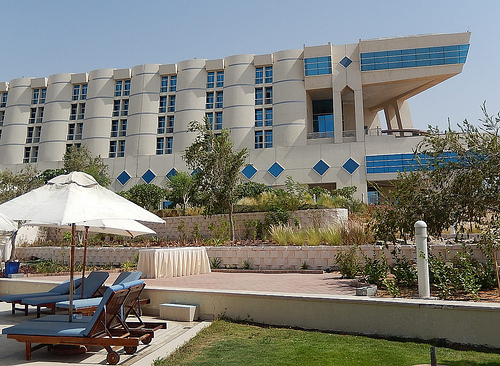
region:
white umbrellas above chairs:
[22, 177, 148, 239]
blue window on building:
[306, 52, 336, 81]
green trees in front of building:
[403, 165, 490, 217]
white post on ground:
[406, 216, 431, 303]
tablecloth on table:
[130, 239, 225, 284]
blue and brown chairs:
[2, 282, 169, 352]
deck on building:
[305, 130, 336, 149]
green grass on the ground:
[218, 320, 310, 355]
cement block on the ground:
[352, 283, 383, 305]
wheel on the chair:
[91, 350, 135, 364]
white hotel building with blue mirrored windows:
[0, 28, 497, 213]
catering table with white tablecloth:
[133, 245, 212, 277]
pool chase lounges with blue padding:
[1, 268, 166, 363]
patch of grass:
[148, 315, 498, 365]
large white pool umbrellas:
[2, 170, 167, 342]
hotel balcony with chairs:
[364, 73, 461, 135]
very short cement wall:
[0, 276, 498, 347]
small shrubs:
[333, 243, 497, 298]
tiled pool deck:
[0, 294, 200, 364]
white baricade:
[412, 218, 432, 298]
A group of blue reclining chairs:
[2, 261, 168, 361]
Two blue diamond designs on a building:
[309, 151, 363, 179]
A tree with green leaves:
[176, 118, 268, 244]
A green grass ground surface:
[216, 323, 309, 365]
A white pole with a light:
[402, 216, 435, 301]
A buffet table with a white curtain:
[135, 243, 217, 280]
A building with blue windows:
[5, 28, 497, 210]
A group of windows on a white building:
[21, 56, 299, 103]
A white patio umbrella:
[0, 147, 171, 227]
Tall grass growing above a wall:
[266, 217, 352, 266]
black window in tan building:
[255, 65, 278, 85]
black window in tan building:
[245, 85, 273, 102]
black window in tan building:
[201, 90, 230, 105]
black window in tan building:
[251, 125, 280, 146]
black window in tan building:
[299, 90, 332, 140]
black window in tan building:
[64, 89, 100, 115]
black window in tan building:
[356, 47, 458, 74]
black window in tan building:
[304, 45, 331, 90]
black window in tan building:
[24, 101, 54, 124]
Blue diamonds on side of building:
[110, 162, 367, 184]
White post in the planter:
[400, 208, 439, 301]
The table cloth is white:
[130, 237, 222, 280]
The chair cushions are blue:
[4, 260, 161, 355]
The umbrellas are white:
[11, 159, 152, 279]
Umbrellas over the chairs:
[17, 166, 170, 353]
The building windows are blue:
[0, 27, 480, 203]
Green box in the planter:
[348, 277, 377, 298]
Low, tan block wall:
[26, 237, 469, 272]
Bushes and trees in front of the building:
[121, 163, 339, 217]